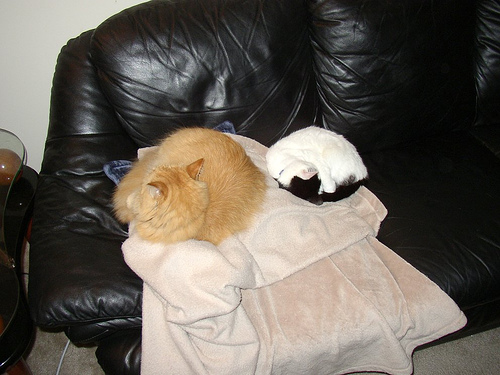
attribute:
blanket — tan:
[282, 241, 363, 290]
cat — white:
[264, 123, 369, 204]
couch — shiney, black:
[30, 2, 497, 347]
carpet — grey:
[70, 354, 93, 374]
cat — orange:
[111, 123, 265, 240]